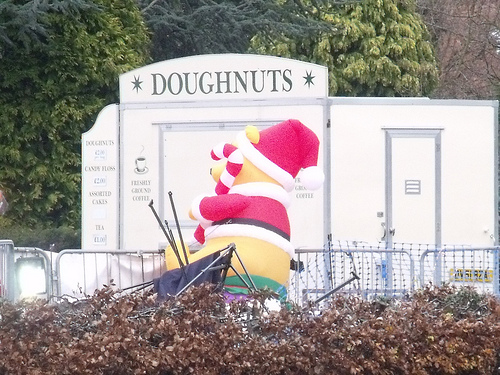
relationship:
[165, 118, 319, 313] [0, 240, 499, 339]
balloon by fence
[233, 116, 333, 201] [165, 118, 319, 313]
hat on a balloon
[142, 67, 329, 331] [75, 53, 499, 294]
picture on building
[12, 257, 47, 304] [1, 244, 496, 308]
mirror on fence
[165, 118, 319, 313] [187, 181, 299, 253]
balloon wearing a red jacket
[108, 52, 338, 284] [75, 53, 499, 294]
sign above a building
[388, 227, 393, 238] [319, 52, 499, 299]
handle on building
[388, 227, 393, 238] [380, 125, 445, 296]
handle on door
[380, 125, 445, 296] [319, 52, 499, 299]
door of building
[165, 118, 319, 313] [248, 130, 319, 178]
balloon wearing a red hat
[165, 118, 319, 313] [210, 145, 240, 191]
balloon holding candy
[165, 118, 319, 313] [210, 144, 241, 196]
balloon holding candy